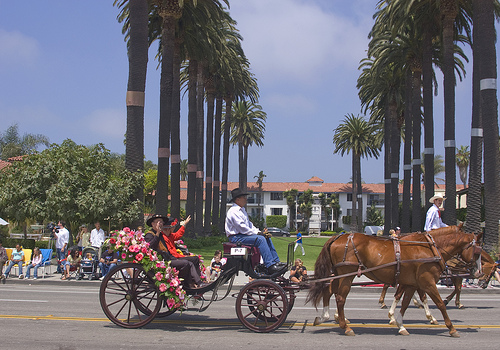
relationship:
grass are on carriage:
[308, 240, 319, 253] [96, 231, 314, 332]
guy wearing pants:
[224, 187, 288, 275] [220, 231, 276, 268]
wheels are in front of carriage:
[228, 276, 298, 334] [96, 231, 314, 332]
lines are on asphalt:
[2, 309, 498, 334] [0, 286, 498, 347]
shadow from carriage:
[103, 307, 293, 336] [96, 231, 314, 332]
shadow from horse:
[312, 314, 487, 335] [302, 228, 484, 339]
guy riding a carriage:
[224, 187, 288, 275] [96, 231, 314, 332]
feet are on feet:
[267, 264, 287, 275] [261, 258, 292, 282]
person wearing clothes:
[161, 214, 206, 282] [161, 225, 186, 258]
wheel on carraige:
[94, 258, 166, 328] [98, 233, 308, 333]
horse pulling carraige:
[302, 228, 484, 339] [98, 233, 308, 333]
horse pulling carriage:
[302, 228, 484, 339] [101, 228, 321, 338]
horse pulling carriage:
[334, 228, 497, 330] [101, 228, 321, 338]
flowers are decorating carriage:
[108, 220, 194, 314] [96, 231, 314, 332]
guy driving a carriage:
[221, 180, 292, 275] [96, 231, 314, 332]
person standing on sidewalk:
[49, 218, 70, 273] [0, 272, 499, 294]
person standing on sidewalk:
[76, 223, 91, 256] [0, 272, 499, 294]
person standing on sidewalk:
[88, 222, 104, 258] [0, 272, 499, 294]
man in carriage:
[143, 213, 207, 289] [98, 185, 296, 333]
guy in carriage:
[224, 187, 288, 275] [98, 185, 296, 333]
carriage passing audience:
[98, 185, 296, 333] [1, 218, 121, 281]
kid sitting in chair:
[3, 242, 26, 282] [6, 248, 33, 278]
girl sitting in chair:
[24, 247, 43, 280] [36, 247, 53, 275]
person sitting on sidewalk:
[289, 256, 308, 284] [0, 265, 498, 295]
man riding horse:
[424, 190, 448, 232] [377, 242, 499, 308]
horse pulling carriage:
[302, 228, 484, 339] [97, 229, 499, 337]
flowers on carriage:
[108, 225, 190, 314] [97, 229, 499, 337]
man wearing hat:
[143, 209, 207, 294] [147, 212, 169, 227]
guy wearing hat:
[224, 187, 288, 275] [228, 185, 253, 206]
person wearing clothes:
[163, 214, 206, 282] [164, 219, 189, 259]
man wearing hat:
[424, 193, 450, 232] [427, 189, 447, 203]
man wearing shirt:
[424, 193, 450, 232] [423, 206, 448, 231]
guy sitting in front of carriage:
[224, 187, 288, 275] [98, 185, 296, 333]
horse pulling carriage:
[302, 228, 484, 339] [98, 185, 296, 333]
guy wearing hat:
[224, 187, 288, 275] [227, 186, 252, 202]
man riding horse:
[424, 193, 450, 232] [443, 246, 499, 309]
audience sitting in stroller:
[0, 220, 120, 281] [77, 247, 101, 280]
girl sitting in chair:
[24, 247, 43, 280] [40, 249, 55, 279]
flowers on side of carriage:
[108, 225, 190, 314] [99, 210, 296, 332]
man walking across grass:
[288, 226, 308, 257] [272, 233, 331, 264]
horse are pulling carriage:
[302, 228, 484, 339] [99, 210, 296, 332]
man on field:
[294, 229, 307, 257] [151, 225, 328, 268]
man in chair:
[143, 213, 207, 289] [118, 207, 210, 331]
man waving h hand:
[143, 213, 207, 289] [148, 213, 169, 239]